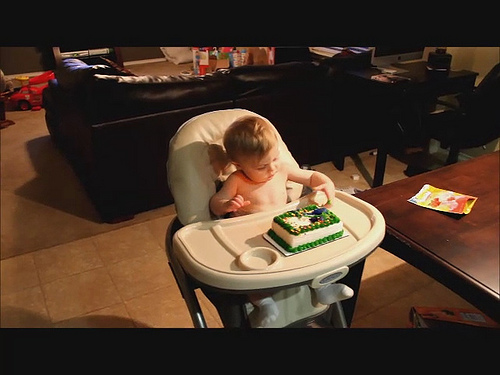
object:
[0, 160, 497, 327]
floor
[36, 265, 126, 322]
tile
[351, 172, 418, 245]
corner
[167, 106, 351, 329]
chair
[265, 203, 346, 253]
cake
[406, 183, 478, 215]
paper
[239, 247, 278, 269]
cupholder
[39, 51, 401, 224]
couch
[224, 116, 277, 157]
blonde hair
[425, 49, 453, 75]
base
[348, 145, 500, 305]
table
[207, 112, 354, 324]
baby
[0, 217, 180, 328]
floor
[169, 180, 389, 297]
tray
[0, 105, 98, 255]
rug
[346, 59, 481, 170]
table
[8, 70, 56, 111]
riding toy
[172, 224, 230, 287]
frame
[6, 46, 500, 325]
kitchen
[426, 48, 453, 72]
lamp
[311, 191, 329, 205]
object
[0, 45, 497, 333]
photo